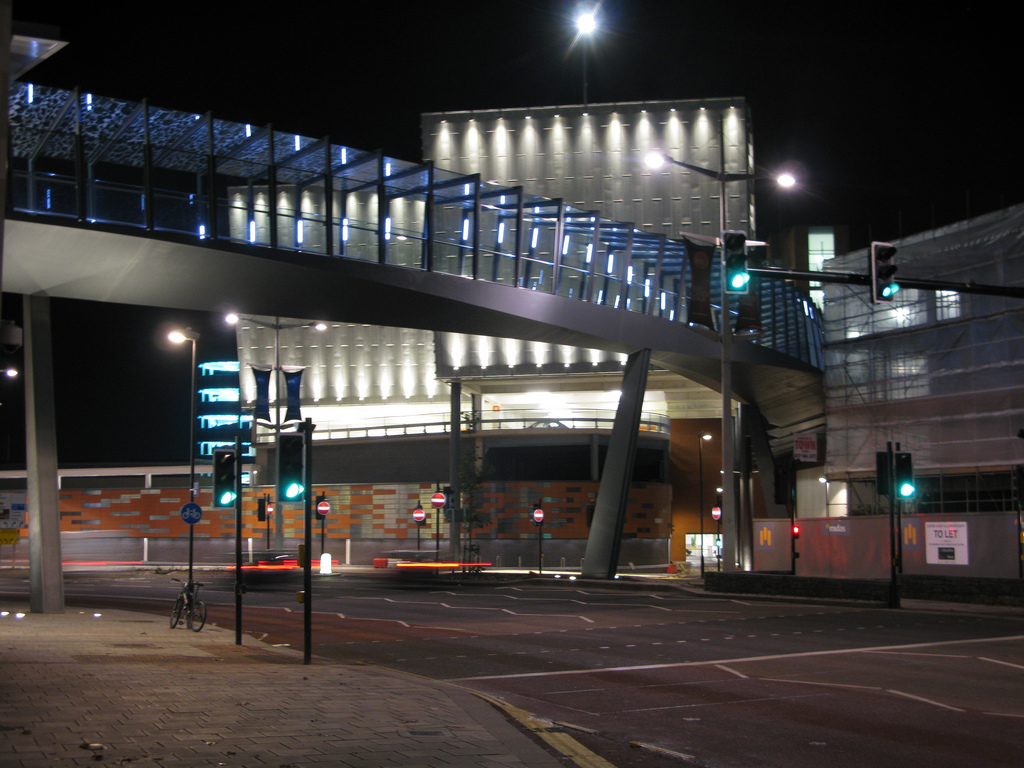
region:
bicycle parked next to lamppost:
[161, 322, 213, 635]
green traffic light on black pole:
[208, 429, 257, 645]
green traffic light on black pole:
[871, 436, 923, 607]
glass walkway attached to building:
[2, 75, 1021, 598]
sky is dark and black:
[0, 0, 1022, 472]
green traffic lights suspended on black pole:
[717, 221, 1021, 323]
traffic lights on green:
[208, 436, 319, 513]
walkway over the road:
[0, 73, 825, 397]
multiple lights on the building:
[432, 98, 753, 134]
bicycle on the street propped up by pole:
[163, 570, 215, 631]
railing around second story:
[300, 405, 665, 437]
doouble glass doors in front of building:
[680, 530, 728, 572]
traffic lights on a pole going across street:
[718, 231, 1017, 302]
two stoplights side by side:
[209, 420, 317, 664]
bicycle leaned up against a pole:
[164, 567, 209, 634]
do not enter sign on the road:
[525, 505, 549, 576]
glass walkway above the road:
[2, 78, 829, 379]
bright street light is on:
[563, 6, 606, 102]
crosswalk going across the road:
[252, 603, 1022, 684]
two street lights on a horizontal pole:
[713, 227, 1015, 305]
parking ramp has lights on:
[192, 353, 262, 465]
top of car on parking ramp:
[515, 415, 574, 436]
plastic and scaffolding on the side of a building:
[818, 205, 1018, 522]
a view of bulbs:
[296, 101, 736, 225]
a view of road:
[496, 680, 596, 735]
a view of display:
[161, 315, 273, 449]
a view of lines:
[410, 607, 617, 764]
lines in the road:
[452, 635, 643, 762]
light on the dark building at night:
[693, 106, 710, 146]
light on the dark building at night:
[664, 106, 684, 149]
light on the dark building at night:
[601, 103, 622, 142]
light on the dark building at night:
[573, 109, 592, 148]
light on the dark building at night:
[542, 112, 568, 152]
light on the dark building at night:
[512, 112, 538, 160]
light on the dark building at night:
[488, 109, 511, 155]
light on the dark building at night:
[462, 117, 483, 150]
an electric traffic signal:
[212, 452, 236, 507]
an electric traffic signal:
[275, 431, 304, 501]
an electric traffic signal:
[898, 450, 917, 499]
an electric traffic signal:
[868, 444, 891, 498]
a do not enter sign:
[427, 488, 446, 511]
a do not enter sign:
[532, 503, 543, 524]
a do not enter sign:
[710, 504, 723, 520]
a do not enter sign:
[411, 504, 425, 521]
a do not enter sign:
[314, 498, 328, 514]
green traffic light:
[886, 471, 929, 513]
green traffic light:
[722, 265, 760, 305]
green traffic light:
[873, 269, 900, 308]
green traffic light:
[276, 468, 300, 508]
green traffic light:
[216, 483, 242, 516]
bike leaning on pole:
[146, 568, 236, 649]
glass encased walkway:
[14, 66, 837, 450]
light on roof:
[563, 4, 636, 148]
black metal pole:
[295, 411, 328, 671]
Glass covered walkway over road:
[6, 73, 814, 611]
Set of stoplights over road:
[217, 227, 929, 671]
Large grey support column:
[585, 348, 652, 592]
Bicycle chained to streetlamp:
[160, 326, 214, 630]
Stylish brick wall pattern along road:
[5, 483, 683, 572]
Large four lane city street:
[6, 410, 1022, 739]